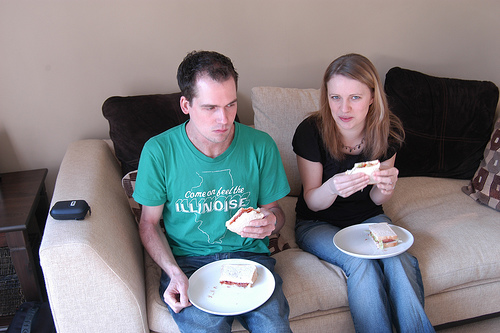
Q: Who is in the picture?
A: A man and a woman.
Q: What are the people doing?
A: Eating.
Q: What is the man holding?
A: A sandwich.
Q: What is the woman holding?
A: A sandwich.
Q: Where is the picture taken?
A: A living room.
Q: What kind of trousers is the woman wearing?
A: Jeans.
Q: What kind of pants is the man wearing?
A: Jeans.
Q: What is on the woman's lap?
A: A plate.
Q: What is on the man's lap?
A: A plate.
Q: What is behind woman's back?
A: Light colored pillow.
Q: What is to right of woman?
A: A square pillow.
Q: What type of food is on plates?
A: Sandwiches.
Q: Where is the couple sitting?
A: On a couch.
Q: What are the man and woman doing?
A: Eating sandwiches.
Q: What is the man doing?
A: Eating a sandwich.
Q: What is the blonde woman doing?
A: Eating a sandwich.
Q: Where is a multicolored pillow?
A: Far right side of couch.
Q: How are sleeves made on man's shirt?
A: Short sleeved.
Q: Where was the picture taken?
A: In a living room.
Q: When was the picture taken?
A: Daytime.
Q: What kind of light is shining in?
A: Sunlight.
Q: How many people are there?
A: Two.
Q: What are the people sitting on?
A: A couch.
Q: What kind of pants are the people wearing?
A: Jeans.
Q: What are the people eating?
A: Sandwiches.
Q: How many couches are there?
A: One.